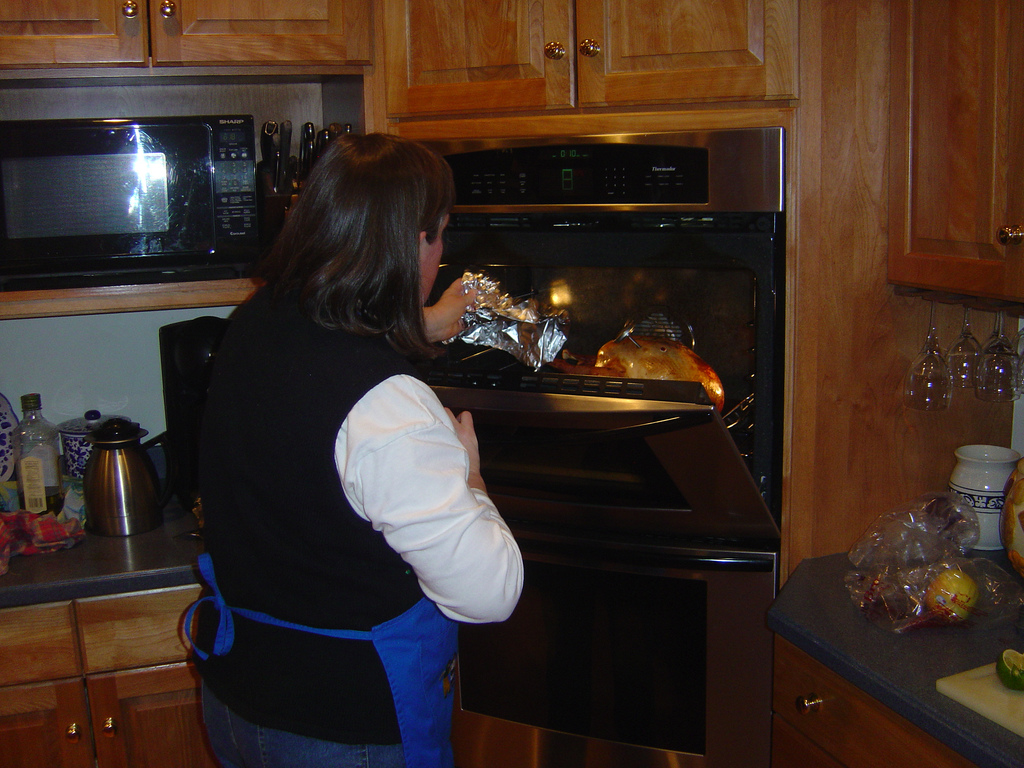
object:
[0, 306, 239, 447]
wall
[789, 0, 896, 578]
wall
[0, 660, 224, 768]
cabinet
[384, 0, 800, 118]
cabinet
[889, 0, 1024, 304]
cabinet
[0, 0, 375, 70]
cabinet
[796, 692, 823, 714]
handle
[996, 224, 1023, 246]
handle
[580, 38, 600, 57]
handle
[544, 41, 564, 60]
handle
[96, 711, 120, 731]
handle